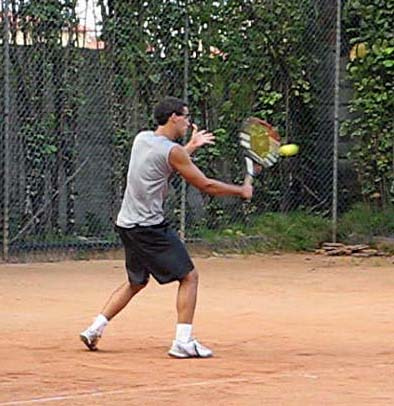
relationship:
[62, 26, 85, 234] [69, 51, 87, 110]
tree has green leaves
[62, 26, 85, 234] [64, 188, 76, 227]
tree has brown bark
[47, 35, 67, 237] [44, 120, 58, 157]
tree has green leaves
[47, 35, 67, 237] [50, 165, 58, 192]
tree has brown bark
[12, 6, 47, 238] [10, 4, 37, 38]
tree has green leaves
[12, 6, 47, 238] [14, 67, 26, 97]
tree has brown bark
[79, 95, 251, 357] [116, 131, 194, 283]
man wearing tennis outfit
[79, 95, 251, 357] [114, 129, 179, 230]
man wearing grey shirt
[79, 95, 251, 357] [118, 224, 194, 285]
man wearing black shorts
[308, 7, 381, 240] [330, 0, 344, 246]
length fence has pole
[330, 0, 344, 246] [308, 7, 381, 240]
pole of length fence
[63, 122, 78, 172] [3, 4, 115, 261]
tree trunk through length fence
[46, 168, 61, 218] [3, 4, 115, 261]
tree trunk through length fence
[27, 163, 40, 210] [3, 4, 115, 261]
tree trunk through length fence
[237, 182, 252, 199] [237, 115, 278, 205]
hand holding tennis racket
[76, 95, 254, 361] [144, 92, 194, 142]
man has head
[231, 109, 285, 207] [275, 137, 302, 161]
tennis racket below tennis ball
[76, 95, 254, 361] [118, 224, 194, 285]
man wears black shorts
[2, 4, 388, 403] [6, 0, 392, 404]
picture in day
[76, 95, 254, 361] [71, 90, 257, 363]
man wears shorts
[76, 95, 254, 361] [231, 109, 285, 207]
man holds tennis racket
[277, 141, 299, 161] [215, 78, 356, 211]
ball in air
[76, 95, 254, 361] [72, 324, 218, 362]
man wears shoes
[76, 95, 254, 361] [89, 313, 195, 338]
man wears socks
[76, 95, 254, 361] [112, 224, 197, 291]
man wears shorts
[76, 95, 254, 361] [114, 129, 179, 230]
man wears grey shirt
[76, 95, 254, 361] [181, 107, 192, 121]
man wears eyeglasses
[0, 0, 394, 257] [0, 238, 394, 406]
length fence wears court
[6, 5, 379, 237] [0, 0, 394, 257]
trees behind length fence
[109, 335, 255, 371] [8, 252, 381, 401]
clay on court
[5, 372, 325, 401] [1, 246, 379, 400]
lines on clay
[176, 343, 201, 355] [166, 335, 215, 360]
mark on shoes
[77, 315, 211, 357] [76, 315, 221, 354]
sneakers on feet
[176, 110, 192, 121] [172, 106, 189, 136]
eyeglasses on face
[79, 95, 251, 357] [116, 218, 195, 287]
man wearing shorts